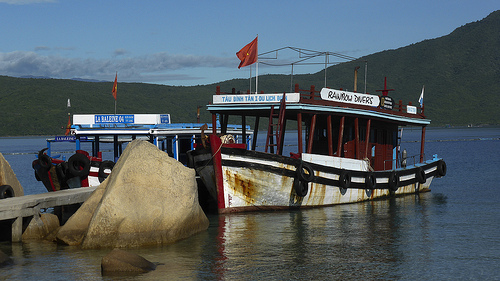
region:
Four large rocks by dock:
[0, 147, 214, 271]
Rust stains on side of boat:
[221, 171, 446, 208]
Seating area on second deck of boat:
[212, 48, 422, 109]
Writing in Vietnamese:
[207, 87, 303, 107]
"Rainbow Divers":
[317, 77, 382, 112]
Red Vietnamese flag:
[228, 30, 270, 100]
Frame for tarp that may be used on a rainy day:
[242, 42, 361, 90]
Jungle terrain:
[4, 1, 491, 136]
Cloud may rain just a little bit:
[4, 51, 136, 82]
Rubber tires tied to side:
[295, 158, 448, 190]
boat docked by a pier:
[200, 30, 456, 227]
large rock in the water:
[58, 139, 220, 261]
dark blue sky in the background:
[14, 0, 413, 35]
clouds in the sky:
[4, 43, 224, 74]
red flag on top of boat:
[223, 25, 267, 88]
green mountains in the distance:
[415, 12, 498, 135]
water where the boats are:
[239, 221, 496, 268]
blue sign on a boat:
[89, 112, 139, 130]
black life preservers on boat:
[32, 152, 96, 185]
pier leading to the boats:
[4, 189, 90, 241]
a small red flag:
[230, 27, 281, 102]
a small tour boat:
[196, 28, 468, 234]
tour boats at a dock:
[20, 30, 475, 262]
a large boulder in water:
[48, 132, 217, 254]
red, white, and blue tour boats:
[30, 31, 462, 241]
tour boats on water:
[21, 12, 468, 254]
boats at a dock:
[15, 13, 467, 239]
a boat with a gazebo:
[188, 72, 463, 232]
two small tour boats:
[27, 33, 461, 255]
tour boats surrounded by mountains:
[16, 7, 463, 241]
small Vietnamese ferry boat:
[211, 32, 436, 220]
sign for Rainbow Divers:
[312, 78, 450, 125]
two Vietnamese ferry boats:
[40, 99, 196, 195]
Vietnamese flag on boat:
[207, 32, 354, 123]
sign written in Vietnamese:
[200, 84, 304, 115]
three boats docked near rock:
[32, 27, 415, 252]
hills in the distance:
[22, 41, 424, 147]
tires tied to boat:
[280, 163, 447, 195]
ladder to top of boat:
[244, 104, 309, 156]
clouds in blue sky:
[17, 44, 212, 98]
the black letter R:
[323, 84, 333, 101]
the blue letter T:
[216, 93, 230, 104]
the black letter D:
[352, 86, 359, 107]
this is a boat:
[172, 27, 468, 232]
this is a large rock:
[36, 124, 241, 269]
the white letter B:
[95, 112, 109, 126]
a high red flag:
[231, 22, 285, 97]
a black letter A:
[331, 86, 339, 102]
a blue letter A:
[223, 90, 229, 102]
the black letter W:
[346, 92, 353, 101]